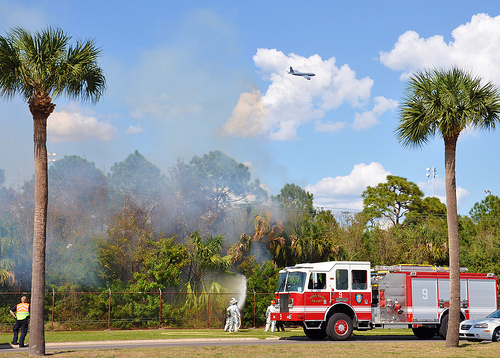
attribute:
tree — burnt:
[97, 202, 157, 288]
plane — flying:
[287, 63, 317, 84]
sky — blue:
[1, 0, 499, 229]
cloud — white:
[47, 12, 500, 230]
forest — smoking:
[0, 148, 498, 330]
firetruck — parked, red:
[268, 261, 500, 340]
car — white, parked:
[460, 306, 500, 342]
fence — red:
[0, 288, 276, 330]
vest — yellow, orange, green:
[14, 302, 29, 321]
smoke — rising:
[2, 4, 306, 288]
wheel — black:
[326, 310, 355, 342]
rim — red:
[334, 321, 350, 335]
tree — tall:
[0, 26, 106, 358]